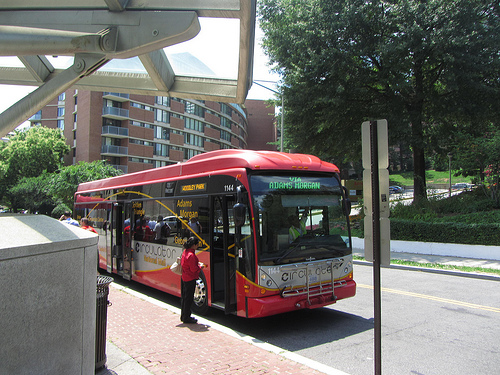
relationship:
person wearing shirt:
[179, 234, 203, 324] [179, 250, 203, 283]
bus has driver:
[73, 148, 358, 318] [290, 206, 310, 242]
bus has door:
[73, 148, 358, 318] [209, 194, 238, 312]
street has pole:
[207, 263, 498, 374] [369, 119, 384, 372]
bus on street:
[73, 148, 358, 318] [207, 263, 498, 374]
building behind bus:
[25, 53, 281, 172] [73, 148, 358, 318]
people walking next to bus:
[59, 210, 101, 269] [73, 148, 358, 318]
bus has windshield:
[73, 148, 358, 318] [248, 191, 353, 265]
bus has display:
[73, 148, 358, 318] [248, 172, 343, 192]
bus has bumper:
[73, 148, 358, 318] [247, 280, 358, 315]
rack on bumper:
[279, 260, 350, 299] [247, 280, 358, 315]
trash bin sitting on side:
[97, 272, 112, 370] [106, 283, 348, 375]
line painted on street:
[356, 280, 500, 309] [207, 263, 498, 374]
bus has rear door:
[73, 148, 358, 318] [111, 204, 129, 281]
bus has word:
[73, 148, 358, 318] [269, 175, 323, 190]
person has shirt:
[179, 234, 203, 324] [179, 250, 203, 283]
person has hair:
[179, 234, 203, 324] [185, 237, 200, 249]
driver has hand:
[290, 206, 310, 242] [301, 205, 308, 219]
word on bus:
[269, 175, 323, 190] [73, 148, 358, 318]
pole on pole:
[369, 119, 384, 372] [369, 119, 384, 372]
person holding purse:
[179, 234, 203, 324] [171, 255, 183, 281]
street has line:
[207, 263, 498, 374] [356, 280, 500, 309]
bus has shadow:
[73, 148, 358, 318] [97, 266, 379, 353]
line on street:
[356, 280, 500, 309] [207, 263, 498, 374]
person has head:
[179, 234, 203, 324] [185, 236, 201, 251]